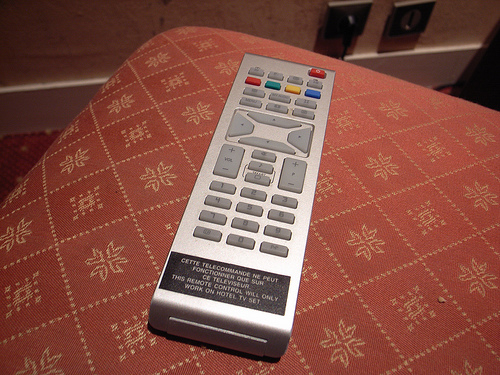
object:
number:
[251, 189, 256, 195]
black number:
[266, 200, 293, 222]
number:
[211, 212, 216, 218]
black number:
[234, 234, 248, 247]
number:
[247, 204, 252, 209]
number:
[254, 175, 261, 179]